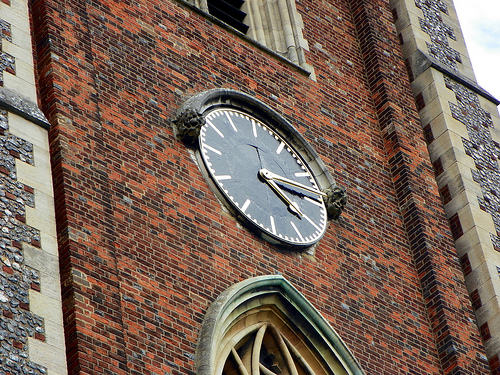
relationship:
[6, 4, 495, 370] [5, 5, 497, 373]
building made of bricks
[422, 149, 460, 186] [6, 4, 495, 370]
ground on side building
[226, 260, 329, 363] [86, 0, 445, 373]
window on wall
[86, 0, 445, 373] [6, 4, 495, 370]
wall of building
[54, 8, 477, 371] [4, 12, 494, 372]
bricks make up wall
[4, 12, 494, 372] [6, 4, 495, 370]
wall of building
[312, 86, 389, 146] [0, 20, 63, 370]
brick on wall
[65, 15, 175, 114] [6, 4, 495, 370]
wall of building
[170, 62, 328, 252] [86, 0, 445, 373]
clock on wall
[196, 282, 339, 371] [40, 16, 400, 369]
entrance to building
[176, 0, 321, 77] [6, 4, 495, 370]
window of building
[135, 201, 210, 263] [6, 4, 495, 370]
bricks on building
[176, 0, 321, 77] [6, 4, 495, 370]
window on building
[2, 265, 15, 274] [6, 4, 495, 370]
bricks on building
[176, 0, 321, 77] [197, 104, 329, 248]
window opening above clock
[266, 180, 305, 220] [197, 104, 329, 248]
small hand on clock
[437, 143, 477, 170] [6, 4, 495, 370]
brick on building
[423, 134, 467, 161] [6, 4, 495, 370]
brick on building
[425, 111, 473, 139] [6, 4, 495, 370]
brick on building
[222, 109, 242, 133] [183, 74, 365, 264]
time indicator on clock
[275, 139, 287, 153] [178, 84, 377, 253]
time indicator on clock